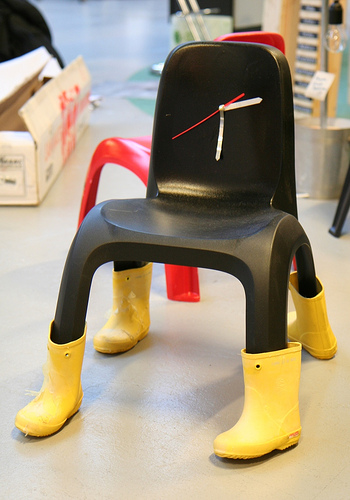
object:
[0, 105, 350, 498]
floor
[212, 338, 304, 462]
boot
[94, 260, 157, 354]
boot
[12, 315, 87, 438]
boot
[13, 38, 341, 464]
chair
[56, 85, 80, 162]
label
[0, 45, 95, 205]
box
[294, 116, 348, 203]
basket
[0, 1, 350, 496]
background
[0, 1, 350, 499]
room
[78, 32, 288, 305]
red chair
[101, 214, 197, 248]
splastic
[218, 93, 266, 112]
hand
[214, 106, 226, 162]
hand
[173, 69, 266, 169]
clock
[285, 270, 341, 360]
boot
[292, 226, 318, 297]
leg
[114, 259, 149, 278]
leg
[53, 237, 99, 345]
leg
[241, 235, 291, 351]
legs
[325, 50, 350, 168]
wall